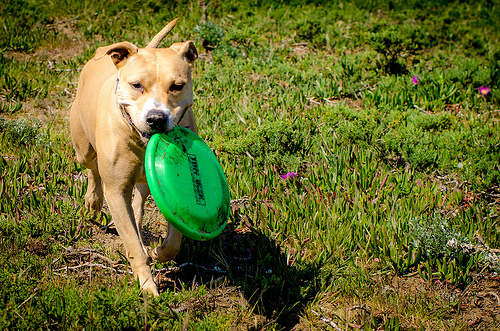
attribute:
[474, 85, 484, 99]
flower — pink, yellow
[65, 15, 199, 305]
dog — tan, tan colored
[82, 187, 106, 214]
paw — dog's, back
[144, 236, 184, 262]
paw — dog's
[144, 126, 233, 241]
frisbee — green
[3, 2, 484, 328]
scene — day time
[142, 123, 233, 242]
disc — green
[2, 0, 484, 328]
lawn — green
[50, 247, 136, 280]
twig — wood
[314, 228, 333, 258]
blade — grass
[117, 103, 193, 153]
mouth — dog's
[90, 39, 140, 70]
ear — flopped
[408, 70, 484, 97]
flowers — purple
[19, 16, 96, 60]
patch — brown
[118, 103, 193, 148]
mouth — dog's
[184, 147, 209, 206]
writing — black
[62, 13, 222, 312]
dog — light brown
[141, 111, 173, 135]
nose — black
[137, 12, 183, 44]
tail — light brown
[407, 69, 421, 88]
flower — purple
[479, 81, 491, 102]
flower — purple